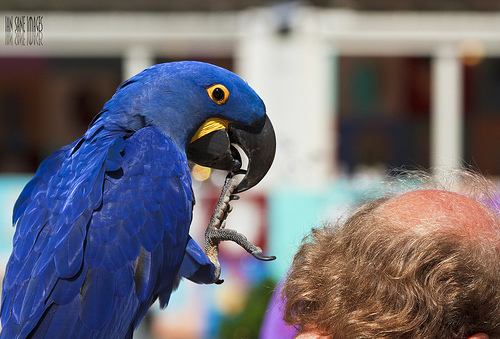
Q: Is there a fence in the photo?
A: No, there are no fences.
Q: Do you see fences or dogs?
A: No, there are no fences or dogs.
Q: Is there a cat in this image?
A: No, there are no cats.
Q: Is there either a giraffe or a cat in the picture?
A: No, there are no cats or giraffes.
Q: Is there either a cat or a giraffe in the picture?
A: No, there are no cats or giraffes.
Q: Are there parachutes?
A: No, there are no parachutes.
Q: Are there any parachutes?
A: No, there are no parachutes.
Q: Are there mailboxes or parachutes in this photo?
A: No, there are no parachutes or mailboxes.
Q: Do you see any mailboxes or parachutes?
A: No, there are no parachutes or mailboxes.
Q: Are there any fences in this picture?
A: No, there are no fences.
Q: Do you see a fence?
A: No, there are no fences.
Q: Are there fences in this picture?
A: No, there are no fences.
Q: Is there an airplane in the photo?
A: No, there are no airplanes.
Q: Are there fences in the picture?
A: No, there are no fences.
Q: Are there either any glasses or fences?
A: No, there are no fences or glasses.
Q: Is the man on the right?
A: Yes, the man is on the right of the image.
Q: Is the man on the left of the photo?
A: No, the man is on the right of the image.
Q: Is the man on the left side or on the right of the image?
A: The man is on the right of the image.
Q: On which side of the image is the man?
A: The man is on the right of the image.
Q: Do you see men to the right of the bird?
A: Yes, there is a man to the right of the bird.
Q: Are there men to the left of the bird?
A: No, the man is to the right of the bird.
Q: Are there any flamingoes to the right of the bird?
A: No, there is a man to the right of the bird.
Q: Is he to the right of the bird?
A: Yes, the man is to the right of the bird.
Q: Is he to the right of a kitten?
A: No, the man is to the right of the bird.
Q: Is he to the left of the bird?
A: No, the man is to the right of the bird.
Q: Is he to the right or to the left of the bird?
A: The man is to the right of the bird.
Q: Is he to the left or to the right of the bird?
A: The man is to the right of the bird.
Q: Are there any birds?
A: Yes, there is a bird.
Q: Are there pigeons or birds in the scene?
A: Yes, there is a bird.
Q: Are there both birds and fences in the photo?
A: No, there is a bird but no fences.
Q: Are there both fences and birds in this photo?
A: No, there is a bird but no fences.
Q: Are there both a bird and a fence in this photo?
A: No, there is a bird but no fences.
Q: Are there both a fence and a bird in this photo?
A: No, there is a bird but no fences.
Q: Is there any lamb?
A: No, there are no lambs.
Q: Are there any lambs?
A: No, there are no lambs.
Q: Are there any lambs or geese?
A: No, there are no lambs or geese.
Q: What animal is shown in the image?
A: The animal is a bird.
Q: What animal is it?
A: The animal is a bird.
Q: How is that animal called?
A: This is a bird.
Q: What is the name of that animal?
A: This is a bird.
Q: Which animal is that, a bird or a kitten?
A: This is a bird.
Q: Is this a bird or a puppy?
A: This is a bird.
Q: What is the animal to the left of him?
A: The animal is a bird.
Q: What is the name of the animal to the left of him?
A: The animal is a bird.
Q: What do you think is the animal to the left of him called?
A: The animal is a bird.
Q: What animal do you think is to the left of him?
A: The animal is a bird.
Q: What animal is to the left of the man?
A: The animal is a bird.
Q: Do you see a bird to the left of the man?
A: Yes, there is a bird to the left of the man.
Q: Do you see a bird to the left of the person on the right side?
A: Yes, there is a bird to the left of the man.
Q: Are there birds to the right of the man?
A: No, the bird is to the left of the man.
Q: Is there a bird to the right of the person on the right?
A: No, the bird is to the left of the man.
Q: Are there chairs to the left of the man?
A: No, there is a bird to the left of the man.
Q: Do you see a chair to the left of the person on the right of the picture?
A: No, there is a bird to the left of the man.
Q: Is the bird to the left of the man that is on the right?
A: Yes, the bird is to the left of the man.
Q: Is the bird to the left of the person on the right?
A: Yes, the bird is to the left of the man.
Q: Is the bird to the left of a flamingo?
A: No, the bird is to the left of the man.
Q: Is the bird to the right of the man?
A: No, the bird is to the left of the man.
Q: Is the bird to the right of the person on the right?
A: No, the bird is to the left of the man.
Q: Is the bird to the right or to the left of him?
A: The bird is to the left of the man.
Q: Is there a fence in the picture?
A: No, there are no fences.